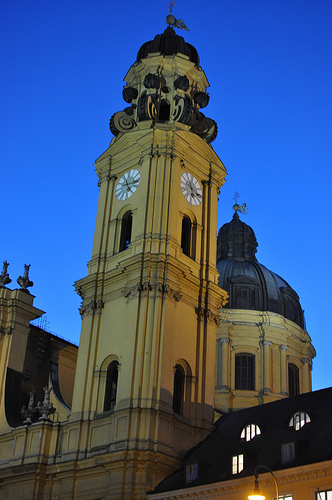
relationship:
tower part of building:
[64, 1, 231, 425] [1, 1, 329, 497]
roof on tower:
[108, 27, 219, 141] [69, 4, 229, 497]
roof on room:
[216, 212, 306, 329] [232, 276, 265, 309]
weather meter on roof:
[165, 3, 190, 33] [137, 27, 200, 73]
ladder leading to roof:
[36, 314, 48, 369] [0, 323, 78, 350]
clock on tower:
[173, 169, 204, 209] [63, 16, 233, 478]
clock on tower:
[173, 169, 204, 209] [64, 1, 231, 425]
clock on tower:
[113, 167, 141, 203] [69, 4, 229, 497]